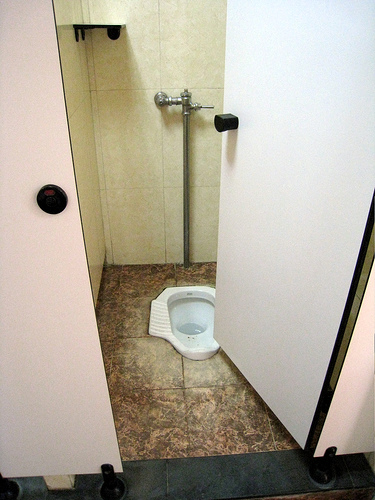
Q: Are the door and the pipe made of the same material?
A: No, the door is made of wood and the pipe is made of metal.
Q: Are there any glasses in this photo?
A: No, there are no glasses.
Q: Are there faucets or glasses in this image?
A: No, there are no glasses or faucets.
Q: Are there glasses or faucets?
A: No, there are no glasses or faucets.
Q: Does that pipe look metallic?
A: Yes, the pipe is metallic.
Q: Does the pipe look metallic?
A: Yes, the pipe is metallic.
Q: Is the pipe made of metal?
A: Yes, the pipe is made of metal.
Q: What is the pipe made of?
A: The pipe is made of metal.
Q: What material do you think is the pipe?
A: The pipe is made of metal.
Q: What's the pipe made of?
A: The pipe is made of metal.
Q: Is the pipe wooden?
A: No, the pipe is metallic.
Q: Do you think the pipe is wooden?
A: No, the pipe is metallic.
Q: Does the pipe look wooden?
A: No, the pipe is metallic.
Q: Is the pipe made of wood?
A: No, the pipe is made of metal.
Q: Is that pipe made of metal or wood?
A: The pipe is made of metal.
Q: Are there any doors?
A: Yes, there is a door.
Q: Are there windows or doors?
A: Yes, there is a door.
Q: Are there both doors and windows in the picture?
A: No, there is a door but no windows.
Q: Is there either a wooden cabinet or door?
A: Yes, there is a wood door.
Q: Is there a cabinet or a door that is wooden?
A: Yes, the door is wooden.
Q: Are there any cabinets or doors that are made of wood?
A: Yes, the door is made of wood.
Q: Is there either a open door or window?
A: Yes, there is an open door.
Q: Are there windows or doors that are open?
A: Yes, the door is open.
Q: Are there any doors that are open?
A: Yes, there is an open door.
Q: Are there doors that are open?
A: Yes, there is a door that is open.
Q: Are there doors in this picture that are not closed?
A: Yes, there is a open door.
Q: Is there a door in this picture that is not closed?
A: Yes, there is a open door.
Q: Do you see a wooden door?
A: Yes, there is a wood door.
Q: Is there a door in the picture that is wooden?
A: Yes, there is a door that is wooden.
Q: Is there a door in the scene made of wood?
A: Yes, there is a door that is made of wood.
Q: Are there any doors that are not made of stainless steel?
A: Yes, there is a door that is made of wood.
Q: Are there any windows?
A: No, there are no windows.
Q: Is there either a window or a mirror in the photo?
A: No, there are no windows or mirrors.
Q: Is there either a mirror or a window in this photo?
A: No, there are no windows or mirrors.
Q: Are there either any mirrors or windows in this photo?
A: No, there are no windows or mirrors.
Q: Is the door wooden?
A: Yes, the door is wooden.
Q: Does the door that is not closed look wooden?
A: Yes, the door is wooden.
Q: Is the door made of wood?
A: Yes, the door is made of wood.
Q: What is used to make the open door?
A: The door is made of wood.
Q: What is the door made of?
A: The door is made of wood.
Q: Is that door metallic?
A: No, the door is wooden.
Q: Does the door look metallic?
A: No, the door is wooden.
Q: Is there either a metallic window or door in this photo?
A: No, there is a door but it is wooden.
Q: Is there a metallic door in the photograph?
A: No, there is a door but it is wooden.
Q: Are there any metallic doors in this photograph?
A: No, there is a door but it is wooden.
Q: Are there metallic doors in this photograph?
A: No, there is a door but it is wooden.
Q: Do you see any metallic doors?
A: No, there is a door but it is wooden.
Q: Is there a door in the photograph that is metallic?
A: No, there is a door but it is wooden.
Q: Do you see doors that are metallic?
A: No, there is a door but it is wooden.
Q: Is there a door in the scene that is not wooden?
A: No, there is a door but it is wooden.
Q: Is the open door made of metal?
A: No, the door is made of wood.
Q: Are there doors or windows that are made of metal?
A: No, there is a door but it is made of wood.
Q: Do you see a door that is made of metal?
A: No, there is a door but it is made of wood.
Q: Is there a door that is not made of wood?
A: No, there is a door but it is made of wood.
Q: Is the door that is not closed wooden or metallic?
A: The door is wooden.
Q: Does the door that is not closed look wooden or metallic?
A: The door is wooden.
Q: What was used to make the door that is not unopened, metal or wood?
A: The door is made of wood.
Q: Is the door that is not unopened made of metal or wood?
A: The door is made of wood.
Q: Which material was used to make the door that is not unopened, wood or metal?
A: The door is made of wood.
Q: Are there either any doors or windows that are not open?
A: No, there is a door but it is open.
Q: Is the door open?
A: Yes, the door is open.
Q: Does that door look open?
A: Yes, the door is open.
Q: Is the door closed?
A: No, the door is open.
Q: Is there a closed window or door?
A: No, there is a door but it is open.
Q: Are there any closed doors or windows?
A: No, there is a door but it is open.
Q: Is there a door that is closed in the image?
A: No, there is a door but it is open.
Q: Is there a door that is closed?
A: No, there is a door but it is open.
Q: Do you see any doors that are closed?
A: No, there is a door but it is open.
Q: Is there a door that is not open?
A: No, there is a door but it is open.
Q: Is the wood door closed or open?
A: The door is open.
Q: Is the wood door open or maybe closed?
A: The door is open.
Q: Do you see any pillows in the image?
A: No, there are no pillows.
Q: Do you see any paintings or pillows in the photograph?
A: No, there are no pillows or paintings.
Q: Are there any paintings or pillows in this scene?
A: No, there are no pillows or paintings.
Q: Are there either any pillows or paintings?
A: No, there are no pillows or paintings.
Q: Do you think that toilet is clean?
A: Yes, the toilet is clean.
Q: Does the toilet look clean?
A: Yes, the toilet is clean.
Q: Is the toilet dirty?
A: No, the toilet is clean.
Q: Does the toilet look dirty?
A: No, the toilet is clean.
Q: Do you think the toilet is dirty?
A: No, the toilet is clean.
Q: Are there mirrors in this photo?
A: No, there are no mirrors.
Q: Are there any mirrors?
A: No, there are no mirrors.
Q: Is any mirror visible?
A: No, there are no mirrors.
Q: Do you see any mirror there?
A: No, there are no mirrors.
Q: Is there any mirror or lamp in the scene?
A: No, there are no mirrors or lamps.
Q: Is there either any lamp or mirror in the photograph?
A: No, there are no mirrors or lamps.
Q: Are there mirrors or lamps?
A: No, there are no mirrors or lamps.